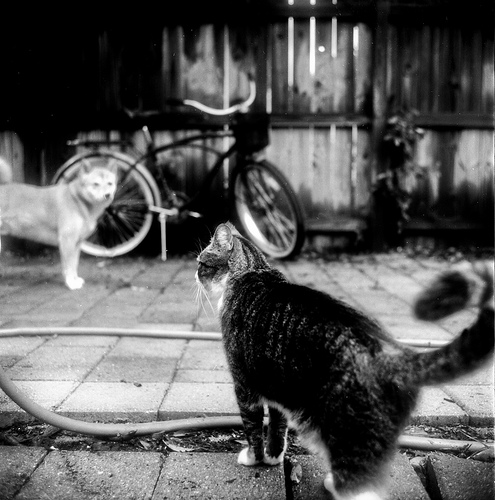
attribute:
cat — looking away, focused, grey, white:
[194, 222, 494, 498]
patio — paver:
[2, 232, 491, 498]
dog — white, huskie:
[1, 158, 118, 289]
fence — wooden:
[2, 2, 494, 250]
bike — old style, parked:
[51, 72, 304, 260]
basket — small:
[232, 110, 272, 155]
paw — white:
[237, 445, 262, 466]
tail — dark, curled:
[392, 261, 494, 387]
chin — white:
[196, 281, 208, 297]